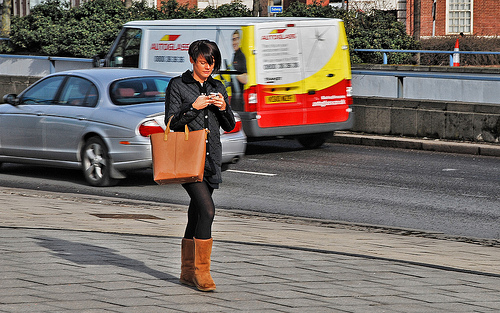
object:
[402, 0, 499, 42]
building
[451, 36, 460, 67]
cone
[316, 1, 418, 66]
bushes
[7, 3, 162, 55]
tree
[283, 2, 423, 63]
tree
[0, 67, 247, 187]
car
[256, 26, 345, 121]
lorry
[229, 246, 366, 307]
floor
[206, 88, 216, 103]
cell phone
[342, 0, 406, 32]
building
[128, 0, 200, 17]
building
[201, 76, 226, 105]
ground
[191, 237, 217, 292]
boot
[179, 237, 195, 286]
boot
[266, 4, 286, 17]
street sign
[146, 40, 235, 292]
lady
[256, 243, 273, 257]
floor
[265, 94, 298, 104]
license plate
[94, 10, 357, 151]
van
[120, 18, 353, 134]
white van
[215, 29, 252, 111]
picture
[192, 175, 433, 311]
floor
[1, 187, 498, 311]
side street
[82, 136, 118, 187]
tire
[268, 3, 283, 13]
sign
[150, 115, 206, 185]
bag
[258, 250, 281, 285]
part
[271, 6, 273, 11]
letter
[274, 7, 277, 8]
letter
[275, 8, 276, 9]
letter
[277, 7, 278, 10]
letter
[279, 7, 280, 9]
letter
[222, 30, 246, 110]
man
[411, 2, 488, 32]
wall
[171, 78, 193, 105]
coat